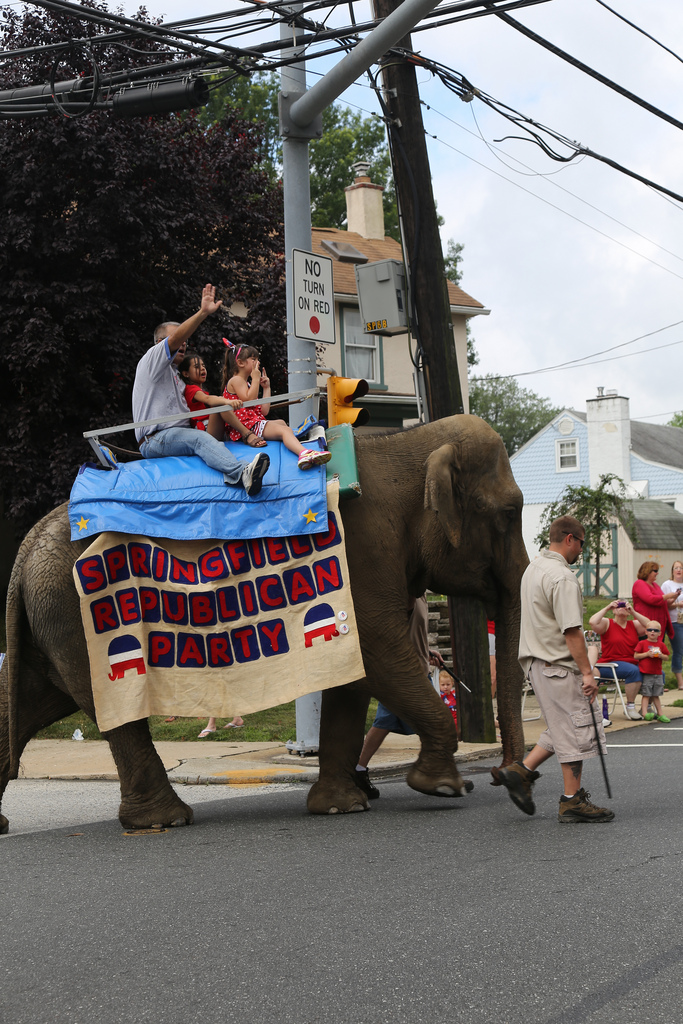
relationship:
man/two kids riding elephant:
[132, 282, 333, 496] [9, 403, 536, 820]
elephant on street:
[9, 403, 536, 820] [9, 722, 662, 1013]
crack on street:
[603, 849, 670, 881] [9, 722, 662, 1013]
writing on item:
[78, 513, 343, 668] [74, 478, 368, 730]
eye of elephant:
[499, 510, 516, 527] [9, 403, 536, 820]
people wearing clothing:
[588, 562, 668, 717] [599, 581, 669, 675]